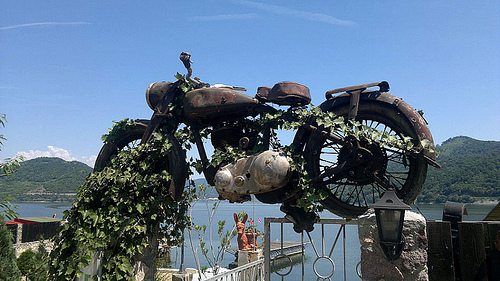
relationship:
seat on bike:
[247, 78, 313, 112] [93, 70, 436, 221]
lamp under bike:
[376, 187, 408, 257] [88, 50, 437, 231]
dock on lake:
[226, 236, 308, 274] [15, 202, 495, 280]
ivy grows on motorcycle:
[58, 129, 448, 271] [94, 71, 441, 219]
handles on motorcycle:
[174, 49, 196, 81] [72, 42, 439, 217]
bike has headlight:
[90, 49, 436, 221] [129, 75, 180, 112]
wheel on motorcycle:
[294, 95, 429, 212] [97, 48, 425, 212]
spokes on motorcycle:
[318, 148, 355, 202] [72, 42, 439, 217]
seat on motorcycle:
[252, 80, 313, 108] [73, 66, 439, 225]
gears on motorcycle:
[207, 117, 274, 153] [72, 42, 439, 217]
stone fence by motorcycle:
[360, 208, 428, 275] [97, 48, 425, 212]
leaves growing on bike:
[58, 144, 172, 279] [88, 50, 437, 231]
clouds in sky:
[308, 1, 390, 62] [164, 2, 448, 84]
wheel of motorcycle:
[330, 130, 389, 186] [72, 42, 439, 217]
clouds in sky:
[8, 144, 97, 164] [1, 1, 498, 50]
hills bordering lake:
[0, 135, 499, 205] [15, 202, 495, 280]